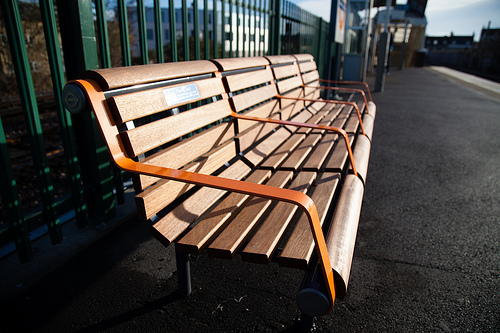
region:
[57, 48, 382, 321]
Wooden bench in front of green metal fence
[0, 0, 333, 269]
Metal fence is green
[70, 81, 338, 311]
Metal arm rest on bench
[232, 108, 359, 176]
Metal arm rest on bench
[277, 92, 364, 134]
Metal arm rest on bench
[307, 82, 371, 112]
Metal arm rest on bench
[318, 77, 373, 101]
Metal arm rest on bench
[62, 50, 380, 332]
Wooden bench on sidewalk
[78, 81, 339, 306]
Metal arm rest on bench is orange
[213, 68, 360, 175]
Metal arm rest on bench is orange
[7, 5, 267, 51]
Tall hunter green wrought iron fence.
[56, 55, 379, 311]
Large wooden bus station bench.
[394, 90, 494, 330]
Black gravel filled sidewalk.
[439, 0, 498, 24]
Evening sky without a visible sun.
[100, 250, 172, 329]
The dark shadow of park bench at a busstop.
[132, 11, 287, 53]
Large government building in the background.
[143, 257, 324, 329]
Cigarette butts strewn about under a bench.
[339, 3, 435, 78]
Covered opening to a train station.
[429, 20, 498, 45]
The tops of various factory buildings.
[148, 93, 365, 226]
The sun shining on the bench in a subway.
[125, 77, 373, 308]
Five chair arms are on the bench.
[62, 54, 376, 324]
A wooden bench is brown with orange arms.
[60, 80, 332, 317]
Round silver end caps are onends of orange arm.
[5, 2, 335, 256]
Vertical green fencing slats ate behind a bench.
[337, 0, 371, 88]
A phone booth is beyond end of the bench.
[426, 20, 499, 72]
The buildings are blurry three chimneys are there.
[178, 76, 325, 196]
Four arms cast shadows on wooden back.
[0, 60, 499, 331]
Pavement extends from the sidewalk on the right to under bench.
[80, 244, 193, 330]
The gray pole is making a shadow.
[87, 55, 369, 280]
Ten gaps are between the slats in each section.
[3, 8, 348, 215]
green gate behind benches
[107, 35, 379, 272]
four benches in a row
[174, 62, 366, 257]
armrests of four benches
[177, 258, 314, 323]
feet of street benches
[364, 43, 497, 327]
sidewalk in front of benches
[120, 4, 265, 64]
building behind fence in background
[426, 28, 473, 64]
house in the background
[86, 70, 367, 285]
first bench in the row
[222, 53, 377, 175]
second bench in row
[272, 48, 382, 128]
third bench in row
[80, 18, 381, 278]
a wooden bench for seating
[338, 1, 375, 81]
a phonebooth for calls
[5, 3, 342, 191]
a green gate along the area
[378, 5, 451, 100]
a building for sitting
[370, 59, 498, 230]
a concrete walk area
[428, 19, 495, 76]
buildings in the background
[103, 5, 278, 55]
a building in the background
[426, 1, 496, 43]
a cloudy sky above the street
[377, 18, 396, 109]
a pole in the background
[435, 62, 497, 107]
a curb along the road